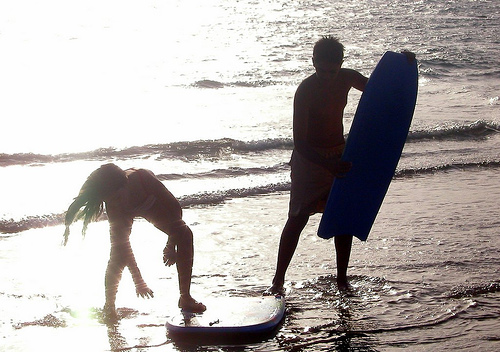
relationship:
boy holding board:
[260, 34, 371, 305] [313, 47, 421, 247]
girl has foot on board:
[58, 158, 214, 327] [313, 47, 421, 247]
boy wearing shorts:
[260, 34, 371, 305] [281, 137, 344, 223]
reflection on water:
[7, 2, 279, 142] [16, 2, 496, 233]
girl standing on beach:
[58, 158, 214, 327] [13, 264, 499, 349]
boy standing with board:
[260, 34, 371, 305] [313, 47, 421, 247]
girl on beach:
[58, 158, 214, 327] [13, 264, 499, 349]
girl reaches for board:
[58, 158, 214, 327] [313, 47, 421, 247]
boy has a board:
[260, 34, 371, 305] [313, 47, 421, 247]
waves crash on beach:
[0, 113, 497, 240] [13, 264, 499, 349]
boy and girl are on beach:
[54, 33, 383, 327] [13, 264, 499, 349]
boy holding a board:
[260, 34, 371, 305] [313, 47, 421, 247]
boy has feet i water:
[260, 34, 371, 305] [16, 2, 496, 233]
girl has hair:
[58, 158, 214, 327] [60, 160, 130, 247]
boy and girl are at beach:
[54, 33, 383, 327] [13, 264, 499, 349]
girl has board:
[58, 158, 214, 327] [313, 47, 421, 247]